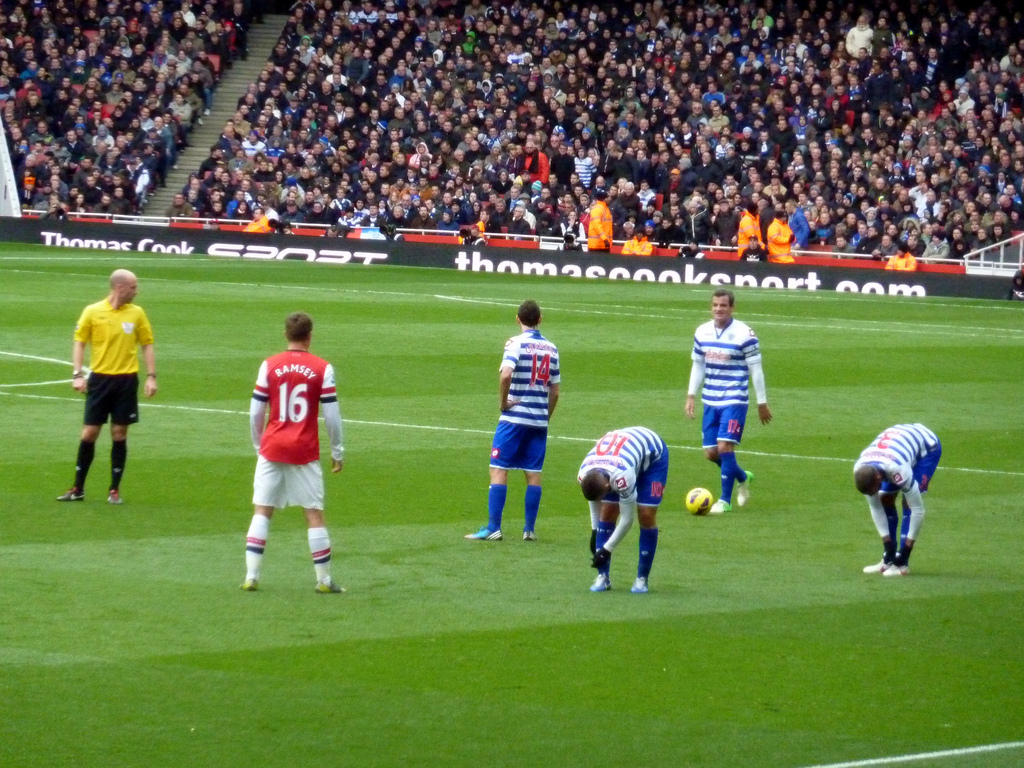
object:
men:
[241, 310, 343, 594]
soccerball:
[685, 488, 713, 516]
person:
[651, 151, 670, 186]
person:
[703, 126, 716, 135]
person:
[644, 97, 664, 122]